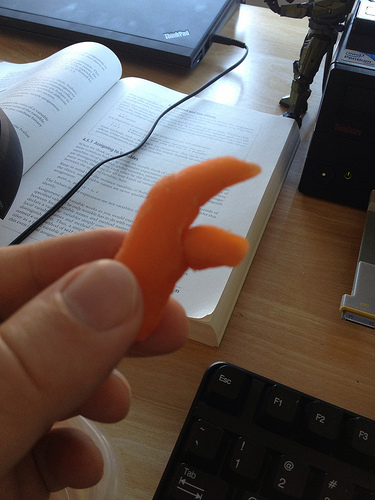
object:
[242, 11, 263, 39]
floor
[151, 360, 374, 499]
keyboard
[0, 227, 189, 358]
fingers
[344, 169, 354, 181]
button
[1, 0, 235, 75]
laptop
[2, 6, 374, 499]
desk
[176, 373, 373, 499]
lettering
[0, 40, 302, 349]
book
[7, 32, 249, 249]
wire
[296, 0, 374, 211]
computer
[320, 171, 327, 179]
light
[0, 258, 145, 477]
finger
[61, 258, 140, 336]
nail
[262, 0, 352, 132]
figurine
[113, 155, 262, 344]
carrot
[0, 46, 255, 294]
words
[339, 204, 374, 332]
plug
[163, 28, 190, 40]
name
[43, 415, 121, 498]
plastic bag